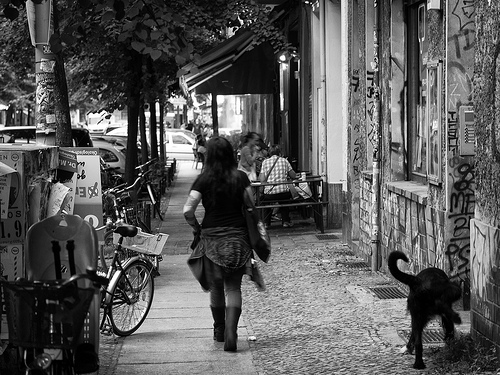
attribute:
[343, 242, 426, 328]
drainage — metal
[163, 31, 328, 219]
porch — wooden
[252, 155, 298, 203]
shirt — plaid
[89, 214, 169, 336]
bike — adult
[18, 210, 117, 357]
seat — baby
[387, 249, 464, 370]
dog — large, black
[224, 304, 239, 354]
boot — leather, calf high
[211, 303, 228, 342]
boot — leather, calf high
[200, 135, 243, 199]
hair — brown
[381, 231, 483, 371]
black animal — long tailed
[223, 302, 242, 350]
boot — black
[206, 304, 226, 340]
boot — black